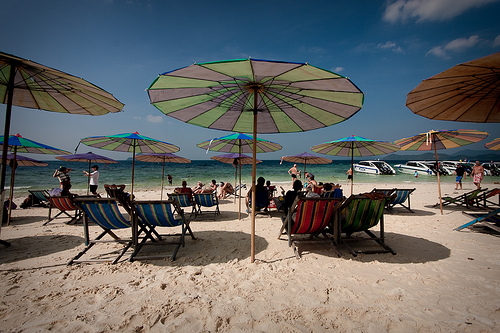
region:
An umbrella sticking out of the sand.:
[140, 46, 380, 261]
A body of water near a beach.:
[0, 142, 493, 193]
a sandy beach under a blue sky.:
[0, 182, 497, 330]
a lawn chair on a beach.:
[277, 170, 412, 268]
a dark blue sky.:
[0, 3, 499, 155]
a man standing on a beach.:
[282, 158, 306, 198]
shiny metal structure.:
[348, 147, 465, 179]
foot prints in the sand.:
[155, 265, 240, 308]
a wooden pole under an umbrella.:
[245, 87, 263, 271]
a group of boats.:
[347, 148, 491, 200]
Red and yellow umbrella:
[142, 36, 367, 131]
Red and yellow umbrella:
[0, 56, 128, 131]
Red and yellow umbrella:
[400, 118, 482, 158]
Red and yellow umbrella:
[317, 130, 404, 162]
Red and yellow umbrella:
[200, 128, 279, 155]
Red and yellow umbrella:
[91, 128, 181, 156]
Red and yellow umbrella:
[0, 134, 64, 154]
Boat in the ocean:
[345, 157, 397, 179]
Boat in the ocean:
[395, 157, 447, 180]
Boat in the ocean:
[437, 153, 492, 190]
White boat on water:
[348, 160, 395, 175]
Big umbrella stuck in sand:
[145, 56, 365, 263]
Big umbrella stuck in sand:
[193, 133, 280, 218]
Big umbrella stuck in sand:
[310, 130, 398, 195]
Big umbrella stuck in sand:
[387, 125, 484, 216]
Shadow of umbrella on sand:
[139, 228, 269, 268]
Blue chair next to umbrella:
[122, 193, 198, 261]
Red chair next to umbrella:
[280, 190, 342, 262]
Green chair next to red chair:
[342, 193, 399, 257]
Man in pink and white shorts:
[470, 158, 485, 185]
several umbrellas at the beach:
[1, 25, 498, 262]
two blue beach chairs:
[62, 190, 195, 277]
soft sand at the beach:
[262, 266, 452, 331]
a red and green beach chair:
[281, 183, 406, 268]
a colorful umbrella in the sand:
[148, 47, 378, 279]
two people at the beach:
[53, 162, 123, 217]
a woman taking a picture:
[79, 158, 105, 198]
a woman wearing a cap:
[80, 159, 105, 190]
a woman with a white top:
[82, 160, 107, 202]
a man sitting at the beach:
[244, 175, 274, 218]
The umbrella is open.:
[206, 149, 261, 218]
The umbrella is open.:
[196, 132, 289, 227]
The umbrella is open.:
[145, 43, 368, 277]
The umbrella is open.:
[133, 150, 194, 230]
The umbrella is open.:
[73, 129, 188, 263]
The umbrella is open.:
[53, 144, 120, 227]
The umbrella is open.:
[1, 150, 50, 237]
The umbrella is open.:
[3, 126, 75, 242]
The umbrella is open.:
[306, 130, 402, 225]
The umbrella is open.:
[391, 122, 487, 230]